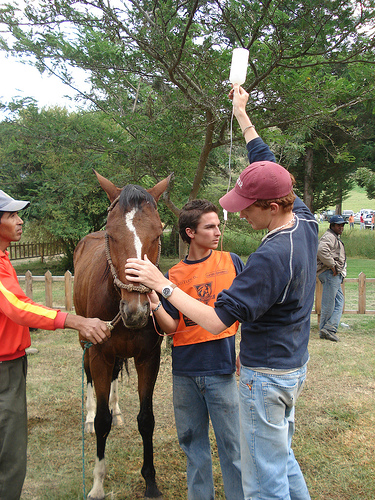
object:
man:
[125, 87, 319, 500]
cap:
[218, 161, 293, 212]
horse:
[73, 169, 170, 500]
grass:
[352, 252, 370, 269]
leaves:
[30, 39, 144, 77]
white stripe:
[124, 204, 142, 259]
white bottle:
[228, 48, 249, 86]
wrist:
[235, 115, 257, 136]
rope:
[105, 234, 134, 293]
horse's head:
[97, 176, 175, 331]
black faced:
[163, 287, 170, 294]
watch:
[162, 283, 175, 299]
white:
[229, 146, 232, 160]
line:
[220, 104, 234, 238]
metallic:
[241, 124, 252, 139]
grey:
[0, 189, 29, 211]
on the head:
[0, 188, 30, 241]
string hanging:
[82, 311, 120, 357]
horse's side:
[73, 233, 108, 351]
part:
[25, 238, 45, 255]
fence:
[24, 268, 71, 307]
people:
[348, 214, 365, 229]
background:
[346, 197, 374, 228]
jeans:
[237, 362, 311, 500]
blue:
[219, 381, 226, 407]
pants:
[169, 368, 310, 500]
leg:
[87, 350, 161, 500]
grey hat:
[0, 190, 30, 211]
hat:
[218, 160, 293, 213]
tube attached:
[221, 47, 248, 224]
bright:
[209, 261, 222, 268]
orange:
[169, 249, 239, 347]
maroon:
[218, 161, 293, 213]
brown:
[44, 273, 51, 300]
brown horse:
[72, 169, 172, 500]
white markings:
[124, 207, 142, 305]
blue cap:
[329, 214, 348, 224]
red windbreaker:
[0, 254, 65, 363]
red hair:
[254, 189, 294, 212]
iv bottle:
[228, 47, 249, 85]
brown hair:
[179, 199, 218, 243]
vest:
[168, 250, 238, 345]